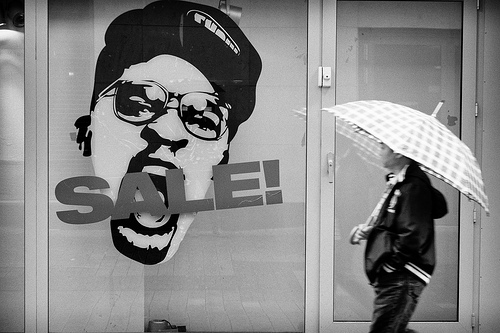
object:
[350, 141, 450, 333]
person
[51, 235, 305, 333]
brick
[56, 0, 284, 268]
sign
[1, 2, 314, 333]
wall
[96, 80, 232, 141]
glasses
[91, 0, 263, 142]
hat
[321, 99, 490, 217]
umbrella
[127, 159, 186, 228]
mouth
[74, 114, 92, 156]
ear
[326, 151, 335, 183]
knob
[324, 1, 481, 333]
door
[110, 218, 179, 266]
beard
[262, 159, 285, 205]
exclamation mark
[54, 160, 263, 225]
letters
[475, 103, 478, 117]
hinge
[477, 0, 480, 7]
hinge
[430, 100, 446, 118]
tip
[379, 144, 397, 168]
face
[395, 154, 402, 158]
ear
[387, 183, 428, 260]
arm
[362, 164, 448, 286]
jacket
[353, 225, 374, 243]
hand